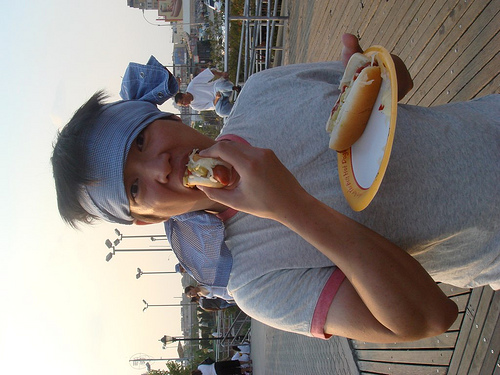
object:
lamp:
[104, 229, 247, 363]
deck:
[258, 16, 499, 341]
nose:
[139, 151, 172, 185]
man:
[171, 68, 236, 119]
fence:
[224, 0, 280, 92]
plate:
[337, 45, 398, 212]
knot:
[108, 55, 180, 102]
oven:
[178, 140, 240, 193]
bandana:
[76, 55, 227, 287]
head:
[50, 91, 225, 234]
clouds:
[0, 0, 184, 375]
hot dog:
[180, 157, 232, 186]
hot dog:
[322, 52, 381, 154]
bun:
[183, 148, 238, 190]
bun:
[325, 51, 382, 151]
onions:
[186, 149, 222, 183]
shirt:
[224, 62, 500, 340]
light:
[104, 237, 179, 265]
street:
[106, 229, 124, 264]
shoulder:
[228, 243, 295, 342]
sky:
[0, 0, 183, 374]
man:
[51, 61, 500, 344]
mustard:
[181, 164, 217, 184]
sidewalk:
[257, 30, 318, 80]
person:
[189, 356, 254, 375]